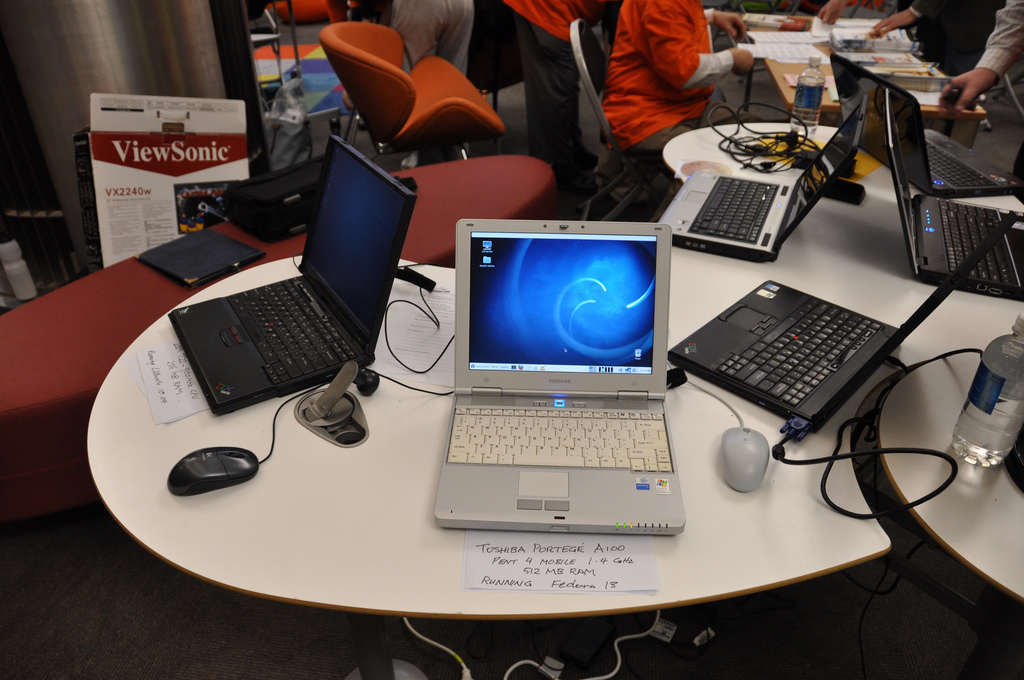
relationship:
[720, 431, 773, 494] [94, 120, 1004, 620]
mouse on desk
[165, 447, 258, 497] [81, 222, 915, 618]
mouse on desk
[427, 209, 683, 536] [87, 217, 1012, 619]
computer on desk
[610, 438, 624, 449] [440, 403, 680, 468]
button on keyboard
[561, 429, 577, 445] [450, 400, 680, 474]
button on keyboard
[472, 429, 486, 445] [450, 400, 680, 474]
button on keyboard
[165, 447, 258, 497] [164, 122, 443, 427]
mouse with laptop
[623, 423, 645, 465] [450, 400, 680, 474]
button on keyboard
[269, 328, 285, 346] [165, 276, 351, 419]
button on keyboard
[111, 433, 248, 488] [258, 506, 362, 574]
mouse on desk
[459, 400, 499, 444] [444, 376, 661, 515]
button on keyboard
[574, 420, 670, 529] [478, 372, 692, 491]
button on keyboard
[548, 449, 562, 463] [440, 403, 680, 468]
button on keyboard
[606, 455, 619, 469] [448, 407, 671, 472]
button on keyboard